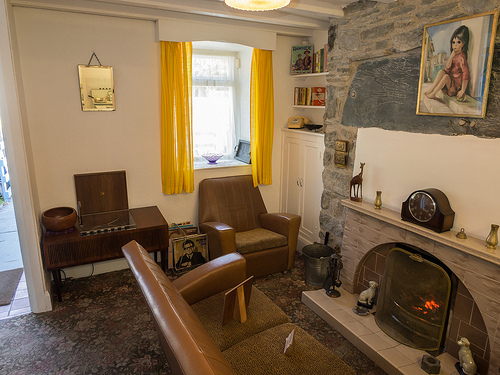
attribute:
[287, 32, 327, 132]
bookshelf — inset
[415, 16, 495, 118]
picture — hanging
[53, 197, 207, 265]
desk — dark brown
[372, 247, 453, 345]
fireplace guard — metal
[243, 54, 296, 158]
curtains — bright yellow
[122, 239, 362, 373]
couch — matching, brown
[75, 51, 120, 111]
mirror — frameless, rectangular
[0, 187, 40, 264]
door — open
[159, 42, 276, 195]
curtains — yellow